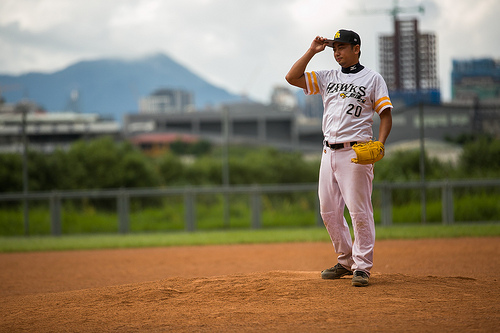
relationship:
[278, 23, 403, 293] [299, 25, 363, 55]
player touching cap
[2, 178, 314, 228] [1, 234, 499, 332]
fence behind court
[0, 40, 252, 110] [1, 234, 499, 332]
hill behind court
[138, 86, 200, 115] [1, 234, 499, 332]
building behind court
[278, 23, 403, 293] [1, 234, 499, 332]
player on field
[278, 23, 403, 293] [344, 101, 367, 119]
player has number 20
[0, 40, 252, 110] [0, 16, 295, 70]
mountains are on background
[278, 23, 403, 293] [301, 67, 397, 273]
player in uniform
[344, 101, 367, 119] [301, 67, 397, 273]
number on a uniform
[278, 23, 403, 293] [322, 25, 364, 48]
player wearing cap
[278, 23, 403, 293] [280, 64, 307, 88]
person has elbow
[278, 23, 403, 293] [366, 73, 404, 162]
player seen left arm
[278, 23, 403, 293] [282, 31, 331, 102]
player has right arm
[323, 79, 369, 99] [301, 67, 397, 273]
name front of uniform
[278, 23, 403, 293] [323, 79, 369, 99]
player for hawks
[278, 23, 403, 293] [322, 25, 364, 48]
man touching cap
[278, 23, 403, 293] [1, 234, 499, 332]
player standing in dirt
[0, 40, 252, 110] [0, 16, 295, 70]
mountain in background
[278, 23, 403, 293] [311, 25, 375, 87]
man has head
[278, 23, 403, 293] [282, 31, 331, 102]
man has arm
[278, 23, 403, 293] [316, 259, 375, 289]
man has feet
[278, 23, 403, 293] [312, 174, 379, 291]
player has legs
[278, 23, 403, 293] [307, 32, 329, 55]
man has hand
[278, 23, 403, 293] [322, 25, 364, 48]
man wearing cap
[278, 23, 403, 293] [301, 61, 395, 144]
man wearing shirt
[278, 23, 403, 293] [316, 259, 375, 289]
man wearing shoes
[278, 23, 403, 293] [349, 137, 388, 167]
player wearing glove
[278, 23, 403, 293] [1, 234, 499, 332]
man standing on dirt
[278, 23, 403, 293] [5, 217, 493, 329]
player on court